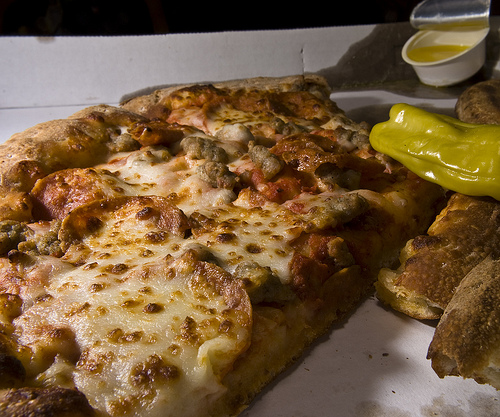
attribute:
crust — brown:
[2, 69, 335, 182]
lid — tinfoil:
[413, 3, 490, 30]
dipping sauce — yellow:
[405, 42, 471, 61]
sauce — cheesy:
[394, 2, 493, 79]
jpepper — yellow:
[366, 100, 498, 202]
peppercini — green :
[366, 101, 498, 206]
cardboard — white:
[359, 332, 423, 407]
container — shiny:
[398, 0, 494, 89]